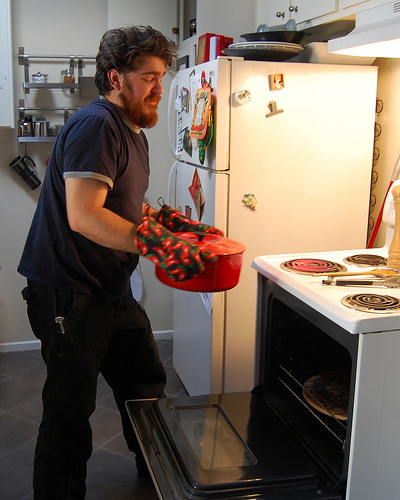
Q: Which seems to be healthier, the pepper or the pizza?
A: The pepper is healthier than the pizza.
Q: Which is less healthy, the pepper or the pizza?
A: The pizza is less healthy than the pepper.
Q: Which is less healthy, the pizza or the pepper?
A: The pizza is less healthy than the pepper.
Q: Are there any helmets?
A: No, there are no helmets.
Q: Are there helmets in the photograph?
A: No, there are no helmets.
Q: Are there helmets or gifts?
A: No, there are no helmets or gifts.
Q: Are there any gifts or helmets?
A: No, there are no helmets or gifts.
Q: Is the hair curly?
A: Yes, the hair is curly.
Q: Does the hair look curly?
A: Yes, the hair is curly.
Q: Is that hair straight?
A: No, the hair is curly.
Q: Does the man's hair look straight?
A: No, the hair is curly.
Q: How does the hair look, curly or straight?
A: The hair is curly.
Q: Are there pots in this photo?
A: Yes, there is a pot.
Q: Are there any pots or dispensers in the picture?
A: Yes, there is a pot.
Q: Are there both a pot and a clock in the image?
A: No, there is a pot but no clocks.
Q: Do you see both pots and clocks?
A: No, there is a pot but no clocks.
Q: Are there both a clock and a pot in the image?
A: No, there is a pot but no clocks.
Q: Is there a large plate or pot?
A: Yes, there is a large pot.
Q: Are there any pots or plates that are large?
A: Yes, the pot is large.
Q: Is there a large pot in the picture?
A: Yes, there is a large pot.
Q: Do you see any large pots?
A: Yes, there is a large pot.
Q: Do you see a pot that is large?
A: Yes, there is a pot that is large.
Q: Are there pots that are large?
A: Yes, there is a pot that is large.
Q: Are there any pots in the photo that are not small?
A: Yes, there is a large pot.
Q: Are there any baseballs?
A: No, there are no baseballs.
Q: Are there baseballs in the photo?
A: No, there are no baseballs.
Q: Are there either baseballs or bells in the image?
A: No, there are no baseballs or bells.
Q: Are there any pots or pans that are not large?
A: No, there is a pot but it is large.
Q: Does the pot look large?
A: Yes, the pot is large.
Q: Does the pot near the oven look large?
A: Yes, the pot is large.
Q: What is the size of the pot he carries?
A: The pot is large.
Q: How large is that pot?
A: The pot is large.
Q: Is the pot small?
A: No, the pot is large.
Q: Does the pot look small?
A: No, the pot is large.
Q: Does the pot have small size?
A: No, the pot is large.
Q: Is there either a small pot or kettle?
A: No, there is a pot but it is large.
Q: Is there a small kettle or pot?
A: No, there is a pot but it is large.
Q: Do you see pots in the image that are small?
A: No, there is a pot but it is large.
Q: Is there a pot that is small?
A: No, there is a pot but it is large.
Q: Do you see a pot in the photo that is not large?
A: No, there is a pot but it is large.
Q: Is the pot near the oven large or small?
A: The pot is large.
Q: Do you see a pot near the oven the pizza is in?
A: Yes, there is a pot near the oven.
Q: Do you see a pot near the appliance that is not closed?
A: Yes, there is a pot near the oven.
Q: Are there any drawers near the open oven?
A: No, there is a pot near the oven.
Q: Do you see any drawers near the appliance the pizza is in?
A: No, there is a pot near the oven.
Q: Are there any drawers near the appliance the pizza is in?
A: No, there is a pot near the oven.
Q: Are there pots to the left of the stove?
A: Yes, there is a pot to the left of the stove.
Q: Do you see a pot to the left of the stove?
A: Yes, there is a pot to the left of the stove.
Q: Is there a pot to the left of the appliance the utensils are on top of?
A: Yes, there is a pot to the left of the stove.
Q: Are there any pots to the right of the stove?
A: No, the pot is to the left of the stove.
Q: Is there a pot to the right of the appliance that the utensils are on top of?
A: No, the pot is to the left of the stove.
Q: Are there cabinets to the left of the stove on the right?
A: No, there is a pot to the left of the stove.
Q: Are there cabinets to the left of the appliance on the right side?
A: No, there is a pot to the left of the stove.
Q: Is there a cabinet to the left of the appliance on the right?
A: No, there is a pot to the left of the stove.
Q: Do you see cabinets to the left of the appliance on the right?
A: No, there is a pot to the left of the stove.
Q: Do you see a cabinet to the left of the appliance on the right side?
A: No, there is a pot to the left of the stove.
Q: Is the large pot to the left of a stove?
A: Yes, the pot is to the left of a stove.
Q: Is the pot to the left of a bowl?
A: No, the pot is to the left of a stove.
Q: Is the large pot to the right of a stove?
A: No, the pot is to the left of a stove.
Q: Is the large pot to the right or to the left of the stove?
A: The pot is to the left of the stove.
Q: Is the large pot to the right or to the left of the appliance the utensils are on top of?
A: The pot is to the left of the stove.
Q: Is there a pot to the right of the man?
A: Yes, there is a pot to the right of the man.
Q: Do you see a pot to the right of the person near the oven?
A: Yes, there is a pot to the right of the man.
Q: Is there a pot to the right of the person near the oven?
A: Yes, there is a pot to the right of the man.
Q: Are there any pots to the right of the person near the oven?
A: Yes, there is a pot to the right of the man.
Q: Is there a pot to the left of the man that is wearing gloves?
A: No, the pot is to the right of the man.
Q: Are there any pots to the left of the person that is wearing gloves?
A: No, the pot is to the right of the man.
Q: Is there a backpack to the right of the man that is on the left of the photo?
A: No, there is a pot to the right of the man.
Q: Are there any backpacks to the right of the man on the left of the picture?
A: No, there is a pot to the right of the man.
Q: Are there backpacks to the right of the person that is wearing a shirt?
A: No, there is a pot to the right of the man.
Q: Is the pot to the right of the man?
A: Yes, the pot is to the right of the man.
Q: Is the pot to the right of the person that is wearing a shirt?
A: Yes, the pot is to the right of the man.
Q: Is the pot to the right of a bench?
A: No, the pot is to the right of the man.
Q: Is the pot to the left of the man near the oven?
A: No, the pot is to the right of the man.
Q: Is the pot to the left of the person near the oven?
A: No, the pot is to the right of the man.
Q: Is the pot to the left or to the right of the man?
A: The pot is to the right of the man.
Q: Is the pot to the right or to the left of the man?
A: The pot is to the right of the man.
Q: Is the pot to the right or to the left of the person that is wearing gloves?
A: The pot is to the right of the man.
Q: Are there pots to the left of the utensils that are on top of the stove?
A: Yes, there is a pot to the left of the utensils.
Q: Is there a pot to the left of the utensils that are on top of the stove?
A: Yes, there is a pot to the left of the utensils.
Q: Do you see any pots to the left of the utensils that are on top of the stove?
A: Yes, there is a pot to the left of the utensils.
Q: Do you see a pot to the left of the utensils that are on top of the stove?
A: Yes, there is a pot to the left of the utensils.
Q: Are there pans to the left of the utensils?
A: No, there is a pot to the left of the utensils.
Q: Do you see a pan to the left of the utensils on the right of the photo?
A: No, there is a pot to the left of the utensils.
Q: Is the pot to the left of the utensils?
A: Yes, the pot is to the left of the utensils.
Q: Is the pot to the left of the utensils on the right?
A: Yes, the pot is to the left of the utensils.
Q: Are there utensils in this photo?
A: Yes, there are utensils.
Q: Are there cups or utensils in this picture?
A: Yes, there are utensils.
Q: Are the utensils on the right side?
A: Yes, the utensils are on the right of the image.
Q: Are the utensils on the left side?
A: No, the utensils are on the right of the image.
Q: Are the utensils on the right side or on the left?
A: The utensils are on the right of the image.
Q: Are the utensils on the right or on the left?
A: The utensils are on the right of the image.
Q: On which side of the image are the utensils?
A: The utensils are on the right of the image.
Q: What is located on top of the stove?
A: The utensils are on top of the stove.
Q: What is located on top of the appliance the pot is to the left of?
A: The utensils are on top of the stove.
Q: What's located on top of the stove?
A: The utensils are on top of the stove.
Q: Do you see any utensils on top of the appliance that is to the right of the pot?
A: Yes, there are utensils on top of the stove.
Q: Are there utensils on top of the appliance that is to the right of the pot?
A: Yes, there are utensils on top of the stove.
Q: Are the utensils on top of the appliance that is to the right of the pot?
A: Yes, the utensils are on top of the stove.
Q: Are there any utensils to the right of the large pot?
A: Yes, there are utensils to the right of the pot.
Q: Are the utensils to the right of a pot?
A: Yes, the utensils are to the right of a pot.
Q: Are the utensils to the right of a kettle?
A: No, the utensils are to the right of a pot.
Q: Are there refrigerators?
A: Yes, there is a refrigerator.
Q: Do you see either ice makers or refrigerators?
A: Yes, there is a refrigerator.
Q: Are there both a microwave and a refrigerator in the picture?
A: No, there is a refrigerator but no microwaves.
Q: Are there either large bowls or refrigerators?
A: Yes, there is a large refrigerator.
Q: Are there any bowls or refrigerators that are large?
A: Yes, the refrigerator is large.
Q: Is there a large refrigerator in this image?
A: Yes, there is a large refrigerator.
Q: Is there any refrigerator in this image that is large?
A: Yes, there is a refrigerator that is large.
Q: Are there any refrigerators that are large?
A: Yes, there is a refrigerator that is large.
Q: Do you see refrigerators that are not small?
A: Yes, there is a large refrigerator.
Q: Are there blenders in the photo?
A: No, there are no blenders.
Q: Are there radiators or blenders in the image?
A: No, there are no blenders or radiators.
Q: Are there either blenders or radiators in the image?
A: No, there are no blenders or radiators.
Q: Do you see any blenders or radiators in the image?
A: No, there are no blenders or radiators.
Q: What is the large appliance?
A: The appliance is a refrigerator.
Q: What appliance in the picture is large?
A: The appliance is a refrigerator.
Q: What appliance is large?
A: The appliance is a refrigerator.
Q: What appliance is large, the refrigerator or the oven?
A: The refrigerator is large.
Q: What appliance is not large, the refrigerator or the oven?
A: The oven is not large.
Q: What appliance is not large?
A: The appliance is an oven.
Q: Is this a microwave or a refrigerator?
A: This is a refrigerator.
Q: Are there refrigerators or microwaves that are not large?
A: No, there is a refrigerator but it is large.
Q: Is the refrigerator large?
A: Yes, the refrigerator is large.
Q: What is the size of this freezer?
A: The freezer is large.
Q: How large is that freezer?
A: The freezer is large.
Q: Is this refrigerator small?
A: No, the refrigerator is large.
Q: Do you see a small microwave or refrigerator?
A: No, there is a refrigerator but it is large.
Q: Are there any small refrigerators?
A: No, there is a refrigerator but it is large.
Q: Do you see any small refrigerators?
A: No, there is a refrigerator but it is large.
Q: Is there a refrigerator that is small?
A: No, there is a refrigerator but it is large.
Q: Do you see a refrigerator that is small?
A: No, there is a refrigerator but it is large.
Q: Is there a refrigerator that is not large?
A: No, there is a refrigerator but it is large.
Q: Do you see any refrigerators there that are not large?
A: No, there is a refrigerator but it is large.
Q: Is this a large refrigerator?
A: Yes, this is a large refrigerator.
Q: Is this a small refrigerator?
A: No, this is a large refrigerator.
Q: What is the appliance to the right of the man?
A: The appliance is a refrigerator.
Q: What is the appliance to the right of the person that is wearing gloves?
A: The appliance is a refrigerator.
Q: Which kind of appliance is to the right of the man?
A: The appliance is a refrigerator.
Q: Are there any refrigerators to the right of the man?
A: Yes, there is a refrigerator to the right of the man.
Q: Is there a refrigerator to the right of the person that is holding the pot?
A: Yes, there is a refrigerator to the right of the man.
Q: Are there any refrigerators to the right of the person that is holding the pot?
A: Yes, there is a refrigerator to the right of the man.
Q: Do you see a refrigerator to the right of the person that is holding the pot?
A: Yes, there is a refrigerator to the right of the man.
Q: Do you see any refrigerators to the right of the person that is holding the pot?
A: Yes, there is a refrigerator to the right of the man.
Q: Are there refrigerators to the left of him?
A: No, the refrigerator is to the right of the man.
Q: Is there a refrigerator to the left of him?
A: No, the refrigerator is to the right of the man.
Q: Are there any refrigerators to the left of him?
A: No, the refrigerator is to the right of the man.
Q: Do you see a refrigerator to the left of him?
A: No, the refrigerator is to the right of the man.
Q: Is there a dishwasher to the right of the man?
A: No, there is a refrigerator to the right of the man.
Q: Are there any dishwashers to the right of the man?
A: No, there is a refrigerator to the right of the man.